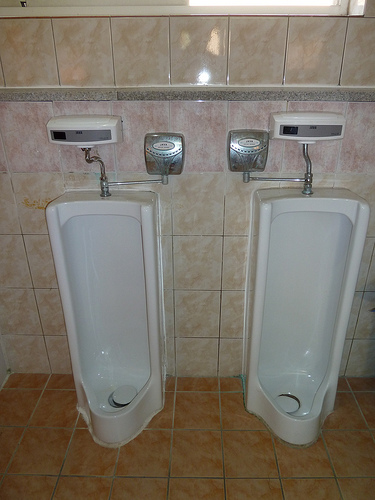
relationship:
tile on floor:
[7, 424, 75, 479] [0, 376, 373, 498]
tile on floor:
[323, 431, 374, 477] [0, 376, 373, 498]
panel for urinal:
[142, 134, 184, 178] [45, 187, 168, 448]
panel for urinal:
[228, 128, 267, 171] [243, 183, 372, 447]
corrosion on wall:
[25, 198, 49, 210] [1, 16, 372, 378]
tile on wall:
[174, 236, 223, 291] [1, 16, 372, 378]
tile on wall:
[174, 290, 222, 338] [1, 16, 372, 378]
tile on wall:
[177, 334, 220, 376] [1, 16, 372, 378]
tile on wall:
[0, 287, 44, 337] [1, 16, 372, 378]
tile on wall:
[0, 337, 50, 376] [1, 16, 372, 378]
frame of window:
[0, 11, 355, 21] [0, 1, 347, 16]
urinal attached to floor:
[243, 183, 372, 447] [0, 376, 373, 498]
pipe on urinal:
[302, 143, 314, 195] [243, 183, 372, 447]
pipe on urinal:
[85, 146, 111, 196] [45, 187, 168, 448]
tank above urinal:
[47, 115, 124, 145] [45, 187, 168, 448]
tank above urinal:
[270, 114, 344, 143] [243, 183, 372, 447]